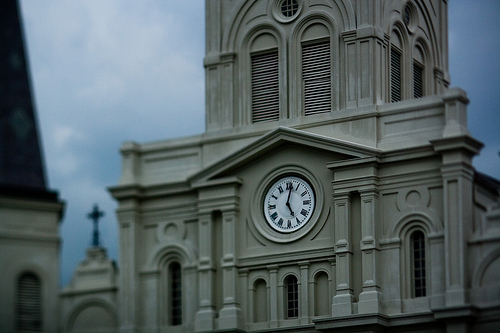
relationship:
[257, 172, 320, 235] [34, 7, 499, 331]
clock on building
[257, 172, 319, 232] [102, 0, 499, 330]
clock on building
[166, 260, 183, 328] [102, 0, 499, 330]
windows on building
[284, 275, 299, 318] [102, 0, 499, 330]
windows on building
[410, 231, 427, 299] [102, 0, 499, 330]
windows on building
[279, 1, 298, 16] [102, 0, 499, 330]
windows on building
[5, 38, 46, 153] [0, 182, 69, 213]
shapes on roof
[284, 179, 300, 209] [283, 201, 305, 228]
minutes past five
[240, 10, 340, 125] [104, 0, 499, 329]
window at top of church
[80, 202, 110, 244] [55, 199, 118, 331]
cross atop building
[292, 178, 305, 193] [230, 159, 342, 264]
roman numeral on clock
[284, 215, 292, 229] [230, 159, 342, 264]
roman numeral on clock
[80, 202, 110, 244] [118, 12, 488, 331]
cross on top of building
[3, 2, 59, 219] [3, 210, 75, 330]
steeple on top of building